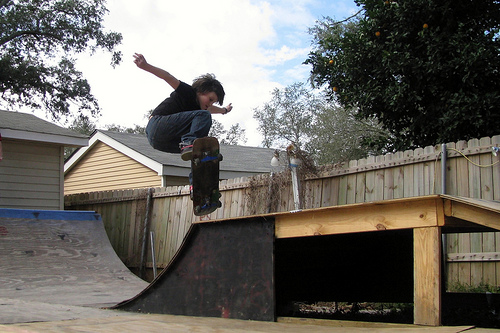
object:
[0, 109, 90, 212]
cream building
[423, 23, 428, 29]
oranges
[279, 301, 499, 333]
ground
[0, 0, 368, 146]
sky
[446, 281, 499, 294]
weeds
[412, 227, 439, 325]
leg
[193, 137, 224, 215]
board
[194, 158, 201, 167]
wheels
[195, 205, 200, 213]
wheels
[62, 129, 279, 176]
roofs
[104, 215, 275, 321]
ramp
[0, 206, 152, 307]
ramp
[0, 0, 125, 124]
tree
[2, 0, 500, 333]
yard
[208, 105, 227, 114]
arm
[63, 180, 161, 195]
siding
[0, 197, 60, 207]
siding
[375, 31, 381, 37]
fruit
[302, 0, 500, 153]
fruit tree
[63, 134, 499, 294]
fence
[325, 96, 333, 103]
leaf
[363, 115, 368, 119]
leaf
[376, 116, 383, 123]
leaf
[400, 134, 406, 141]
leaf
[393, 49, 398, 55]
leaf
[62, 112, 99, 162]
tree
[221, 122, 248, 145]
tree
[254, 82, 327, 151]
tree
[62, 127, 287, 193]
building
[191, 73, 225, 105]
hair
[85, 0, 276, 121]
cloud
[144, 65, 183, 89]
arm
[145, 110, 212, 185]
jeans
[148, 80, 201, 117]
shirt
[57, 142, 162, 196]
shingles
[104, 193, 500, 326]
platform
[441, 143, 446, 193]
pole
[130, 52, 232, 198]
boy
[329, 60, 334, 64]
fruit